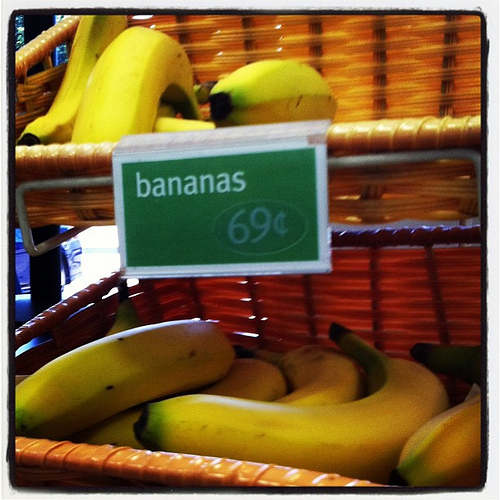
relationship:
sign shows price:
[108, 136, 342, 276] [210, 202, 307, 254]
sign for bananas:
[108, 136, 342, 276] [48, 283, 440, 480]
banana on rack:
[66, 24, 208, 134] [14, 146, 484, 259]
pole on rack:
[359, 152, 416, 167] [14, 146, 484, 259]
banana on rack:
[9, 310, 240, 431] [14, 146, 484, 259]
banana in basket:
[66, 24, 208, 134] [336, 19, 483, 216]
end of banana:
[127, 397, 172, 443] [143, 326, 447, 470]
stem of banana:
[320, 308, 388, 360] [143, 326, 447, 470]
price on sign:
[210, 202, 307, 254] [108, 136, 342, 276]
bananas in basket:
[48, 283, 440, 480] [336, 19, 483, 216]